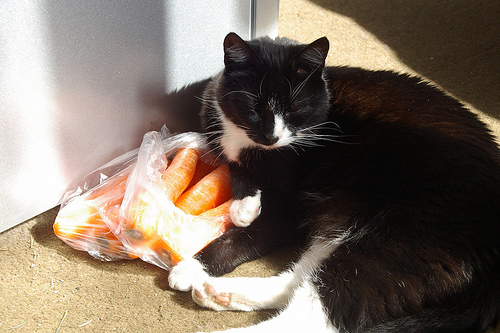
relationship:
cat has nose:
[166, 33, 497, 332] [264, 133, 278, 144]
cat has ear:
[166, 33, 497, 332] [223, 33, 263, 69]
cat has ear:
[166, 33, 497, 332] [293, 36, 328, 73]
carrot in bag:
[54, 162, 133, 240] [52, 124, 248, 273]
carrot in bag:
[127, 133, 200, 244] [52, 124, 248, 273]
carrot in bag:
[155, 196, 233, 265] [52, 124, 248, 273]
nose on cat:
[264, 133, 278, 144] [166, 33, 497, 332]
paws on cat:
[230, 198, 265, 227] [166, 33, 497, 332]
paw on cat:
[169, 255, 207, 295] [166, 33, 497, 332]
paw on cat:
[191, 277, 234, 310] [166, 33, 497, 332]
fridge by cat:
[1, 1, 279, 233] [166, 33, 497, 332]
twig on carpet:
[53, 307, 74, 332] [1, 1, 498, 332]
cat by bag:
[166, 33, 497, 332] [52, 124, 248, 273]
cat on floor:
[166, 33, 497, 332] [1, 1, 498, 332]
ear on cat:
[223, 33, 263, 69] [166, 33, 497, 332]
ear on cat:
[293, 36, 328, 73] [166, 33, 497, 332]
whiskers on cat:
[198, 121, 252, 167] [166, 33, 497, 332]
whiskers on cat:
[292, 120, 361, 157] [166, 33, 497, 332]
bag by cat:
[52, 124, 248, 273] [166, 33, 497, 332]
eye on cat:
[240, 99, 259, 113] [166, 33, 497, 332]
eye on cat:
[284, 103, 306, 116] [166, 33, 497, 332]